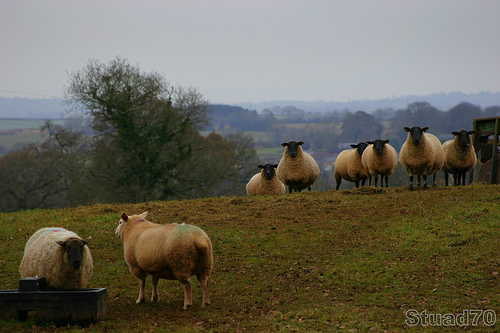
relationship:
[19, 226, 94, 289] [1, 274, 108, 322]
sheep next to water trough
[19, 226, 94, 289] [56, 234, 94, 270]
sheep has face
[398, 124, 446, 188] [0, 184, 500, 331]
sheep on top of hill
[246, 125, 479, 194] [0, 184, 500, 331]
herd on top of hill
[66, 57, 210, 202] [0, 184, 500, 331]
tree on other side of hill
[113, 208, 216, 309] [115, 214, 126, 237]
sheep has face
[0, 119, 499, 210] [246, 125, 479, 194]
valley behind herd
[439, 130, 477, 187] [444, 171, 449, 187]
sheep has leg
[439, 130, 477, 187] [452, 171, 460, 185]
sheep has leg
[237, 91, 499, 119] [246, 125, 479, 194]
mountains behind herd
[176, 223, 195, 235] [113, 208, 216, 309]
mark on top of sheep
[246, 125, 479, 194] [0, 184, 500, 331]
herd standing on top of hill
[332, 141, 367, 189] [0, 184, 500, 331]
sheep standing on top of hill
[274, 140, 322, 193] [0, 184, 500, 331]
sheep standing on top of hill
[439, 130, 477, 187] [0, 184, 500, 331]
sheep standing on top of hill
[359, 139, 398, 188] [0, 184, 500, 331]
sheep standing on top of hill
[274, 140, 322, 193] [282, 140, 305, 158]
sheep has face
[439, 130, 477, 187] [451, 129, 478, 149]
sheep has face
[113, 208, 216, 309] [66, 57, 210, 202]
sheep looking at tree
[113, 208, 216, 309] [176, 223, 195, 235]
sheep has mark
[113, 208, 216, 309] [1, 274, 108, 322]
sheep standing by water trough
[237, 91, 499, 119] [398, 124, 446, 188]
mountains behind sheep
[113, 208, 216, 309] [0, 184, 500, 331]
sheep on hill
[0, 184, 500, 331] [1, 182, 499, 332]
hill covered in grass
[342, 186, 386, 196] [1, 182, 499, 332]
mound of grass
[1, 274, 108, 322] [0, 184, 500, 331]
water trough on top of hill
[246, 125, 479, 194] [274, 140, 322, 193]
herd of sheep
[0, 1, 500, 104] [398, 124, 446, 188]
sky behind sheep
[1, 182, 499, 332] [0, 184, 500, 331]
grass growing on top of hill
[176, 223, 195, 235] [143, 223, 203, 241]
mark on back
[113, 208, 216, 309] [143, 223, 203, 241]
sheep has back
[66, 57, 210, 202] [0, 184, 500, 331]
tree behind hill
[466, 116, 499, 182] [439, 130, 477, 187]
sign near sheep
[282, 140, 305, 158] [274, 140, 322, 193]
face of sheep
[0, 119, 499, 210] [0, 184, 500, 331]
valley behind hill